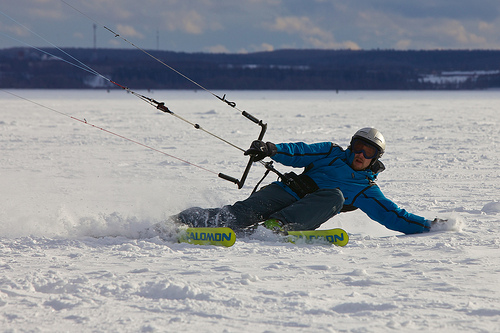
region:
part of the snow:
[293, 275, 333, 303]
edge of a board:
[212, 233, 231, 236]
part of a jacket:
[381, 201, 391, 208]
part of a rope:
[158, 143, 193, 165]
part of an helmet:
[372, 137, 377, 152]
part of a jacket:
[288, 153, 310, 175]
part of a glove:
[261, 152, 266, 164]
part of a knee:
[330, 196, 340, 204]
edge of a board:
[220, 238, 230, 262]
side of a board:
[221, 228, 238, 244]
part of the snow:
[366, 238, 401, 261]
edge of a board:
[219, 235, 232, 242]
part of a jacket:
[391, 211, 403, 219]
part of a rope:
[221, 137, 226, 140]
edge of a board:
[222, 232, 234, 238]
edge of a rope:
[233, 108, 247, 110]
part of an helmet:
[366, 130, 368, 182]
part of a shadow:
[360, 142, 367, 151]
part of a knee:
[327, 198, 338, 203]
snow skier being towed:
[147, 98, 467, 258]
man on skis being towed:
[147, 110, 467, 267]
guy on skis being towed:
[137, 119, 464, 261]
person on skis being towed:
[140, 110, 455, 270]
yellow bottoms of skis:
[140, 222, 365, 253]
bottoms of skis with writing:
[167, 219, 355, 256]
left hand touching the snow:
[379, 177, 471, 259]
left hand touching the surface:
[379, 189, 470, 274]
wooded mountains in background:
[8, 0, 497, 95]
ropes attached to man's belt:
[213, 115, 299, 195]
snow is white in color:
[53, 252, 230, 313]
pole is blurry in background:
[84, 21, 104, 50]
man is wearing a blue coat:
[270, 136, 433, 203]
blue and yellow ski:
[163, 224, 243, 247]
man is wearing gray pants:
[177, 187, 349, 229]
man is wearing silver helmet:
[355, 124, 389, 145]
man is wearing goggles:
[347, 142, 381, 157]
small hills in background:
[259, 45, 497, 88]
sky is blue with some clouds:
[202, 11, 419, 31]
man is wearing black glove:
[243, 141, 280, 165]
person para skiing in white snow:
[162, 98, 389, 259]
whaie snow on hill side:
[14, 101, 78, 145]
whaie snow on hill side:
[24, 156, 91, 194]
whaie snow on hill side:
[13, 218, 122, 287]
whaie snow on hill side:
[127, 256, 262, 304]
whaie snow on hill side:
[277, 244, 395, 318]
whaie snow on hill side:
[364, 247, 458, 309]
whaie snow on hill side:
[392, 99, 469, 146]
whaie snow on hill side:
[95, 126, 164, 191]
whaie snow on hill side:
[264, 90, 312, 135]